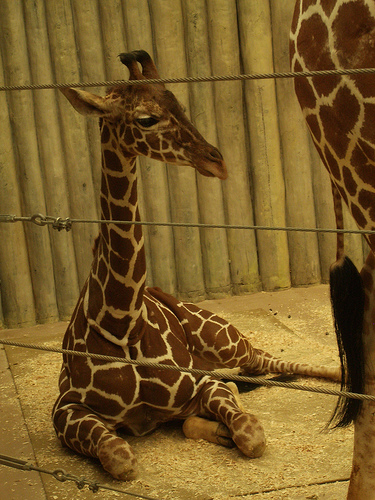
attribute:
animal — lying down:
[52, 29, 320, 468]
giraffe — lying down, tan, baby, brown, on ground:
[51, 59, 316, 463]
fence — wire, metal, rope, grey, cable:
[17, 58, 370, 143]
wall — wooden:
[6, 7, 340, 292]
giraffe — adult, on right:
[278, 7, 368, 196]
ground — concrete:
[238, 270, 338, 322]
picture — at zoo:
[1, 10, 364, 499]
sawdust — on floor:
[161, 444, 327, 478]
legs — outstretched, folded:
[46, 353, 270, 470]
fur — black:
[293, 260, 374, 417]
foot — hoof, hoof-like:
[191, 393, 262, 444]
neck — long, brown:
[90, 110, 143, 237]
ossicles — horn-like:
[117, 34, 169, 75]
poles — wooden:
[0, 8, 83, 312]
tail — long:
[334, 90, 366, 431]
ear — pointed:
[53, 83, 107, 137]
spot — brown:
[107, 165, 129, 213]